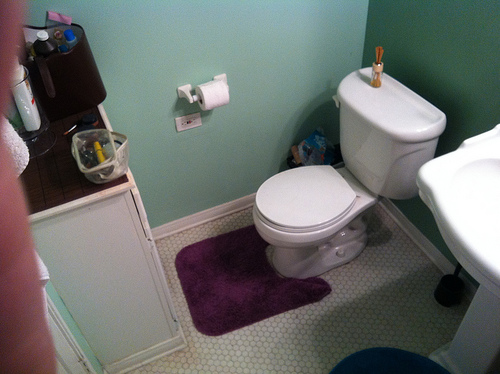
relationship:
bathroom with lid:
[0, 0, 500, 374] [267, 159, 346, 222]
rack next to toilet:
[268, 118, 338, 181] [246, 61, 448, 282]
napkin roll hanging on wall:
[195, 80, 230, 111] [23, 0, 367, 229]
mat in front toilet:
[173, 219, 332, 337] [246, 61, 448, 282]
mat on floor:
[325, 340, 453, 372] [95, 188, 497, 372]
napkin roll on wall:
[195, 80, 230, 111] [150, 33, 219, 78]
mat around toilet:
[175, 223, 333, 336] [246, 61, 448, 282]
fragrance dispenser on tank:
[368, 43, 390, 93] [332, 67, 447, 200]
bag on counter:
[68, 125, 133, 185] [13, 100, 136, 220]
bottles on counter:
[10, 46, 88, 114] [11, 56, 105, 216]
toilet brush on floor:
[437, 265, 473, 308] [152, 147, 498, 370]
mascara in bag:
[91, 139, 106, 164] [70, 127, 130, 184]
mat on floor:
[173, 219, 332, 337] [58, 166, 498, 372]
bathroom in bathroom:
[0, 0, 500, 374] [7, 2, 496, 372]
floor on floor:
[114, 203, 499, 374] [234, 330, 317, 372]